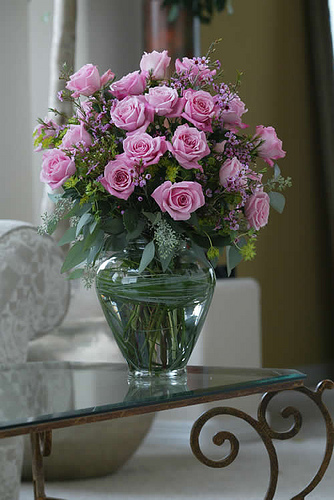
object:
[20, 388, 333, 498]
carpet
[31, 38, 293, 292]
buds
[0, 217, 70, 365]
arm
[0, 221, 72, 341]
design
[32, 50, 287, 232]
flowers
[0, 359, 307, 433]
table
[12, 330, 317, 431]
coffee table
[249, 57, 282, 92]
ground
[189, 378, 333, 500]
designs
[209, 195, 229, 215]
leaves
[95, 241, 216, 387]
vase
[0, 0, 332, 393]
wall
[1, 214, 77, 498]
designer sofa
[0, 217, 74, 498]
couch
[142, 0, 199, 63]
molding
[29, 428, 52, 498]
leg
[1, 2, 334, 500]
background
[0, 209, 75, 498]
chair